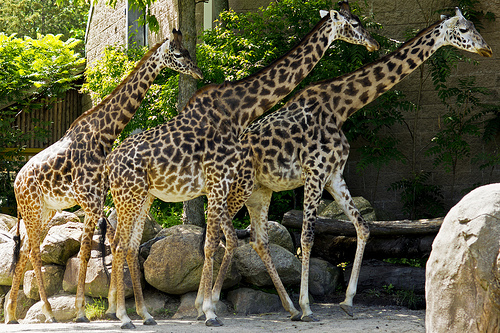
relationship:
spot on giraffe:
[404, 58, 419, 70] [194, 5, 494, 320]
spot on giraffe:
[223, 96, 240, 110] [98, 5, 382, 326]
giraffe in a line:
[221, 9, 481, 306] [7, 6, 491, 326]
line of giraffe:
[7, 6, 491, 326] [221, 9, 481, 306]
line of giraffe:
[7, 6, 491, 326] [98, 5, 382, 326]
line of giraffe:
[7, 6, 491, 326] [7, 27, 212, 319]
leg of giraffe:
[285, 184, 322, 323] [194, 5, 494, 320]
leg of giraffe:
[334, 193, 376, 311] [258, 23, 487, 314]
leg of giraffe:
[245, 185, 305, 321] [194, 5, 494, 320]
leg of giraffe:
[68, 215, 101, 324] [7, 27, 212, 319]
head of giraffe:
[163, 27, 205, 79] [7, 27, 212, 319]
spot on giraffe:
[303, 111, 315, 125] [163, 0, 435, 278]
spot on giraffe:
[270, 134, 286, 152] [163, 0, 435, 278]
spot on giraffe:
[329, 81, 343, 94] [163, 0, 435, 278]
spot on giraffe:
[334, 104, 347, 119] [163, 0, 435, 278]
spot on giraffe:
[318, 90, 332, 103] [163, 0, 435, 278]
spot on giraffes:
[273, 122, 290, 138] [13, 19, 477, 316]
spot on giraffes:
[332, 90, 342, 110] [13, 19, 477, 316]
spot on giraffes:
[325, 78, 344, 94] [13, 19, 477, 316]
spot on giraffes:
[357, 88, 372, 106] [13, 19, 477, 316]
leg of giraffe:
[327, 178, 374, 322] [191, 105, 468, 280]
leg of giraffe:
[290, 178, 330, 324] [191, 105, 468, 280]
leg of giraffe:
[248, 197, 301, 325] [191, 105, 468, 280]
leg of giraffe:
[109, 199, 139, 329] [98, 5, 382, 326]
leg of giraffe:
[216, 205, 237, 310] [98, 5, 382, 326]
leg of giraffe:
[327, 178, 374, 322] [221, 9, 481, 306]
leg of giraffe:
[294, 177, 325, 327] [221, 9, 481, 306]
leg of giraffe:
[244, 196, 300, 323] [221, 9, 481, 306]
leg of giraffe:
[203, 178, 222, 329] [221, 9, 481, 306]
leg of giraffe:
[111, 198, 134, 330] [98, 5, 382, 326]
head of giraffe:
[430, 6, 484, 61] [221, 9, 481, 306]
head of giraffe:
[307, 6, 382, 60] [98, 5, 382, 326]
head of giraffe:
[149, 25, 209, 82] [7, 27, 212, 319]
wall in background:
[362, 78, 499, 197] [7, 18, 481, 139]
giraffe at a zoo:
[221, 9, 481, 306] [5, 2, 484, 327]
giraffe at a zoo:
[98, 5, 382, 326] [5, 2, 484, 327]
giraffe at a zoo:
[7, 27, 212, 319] [5, 2, 484, 327]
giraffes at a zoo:
[13, 19, 477, 316] [5, 2, 484, 327]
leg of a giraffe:
[327, 180, 369, 317] [194, 5, 494, 320]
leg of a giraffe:
[298, 175, 318, 324] [194, 5, 494, 320]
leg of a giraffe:
[244, 196, 300, 323] [194, 5, 494, 320]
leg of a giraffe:
[107, 200, 137, 327] [98, 5, 382, 326]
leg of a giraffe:
[126, 210, 157, 329] [7, 27, 212, 319]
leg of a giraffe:
[16, 195, 59, 326] [7, 7, 197, 326]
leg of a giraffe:
[73, 196, 104, 321] [7, 7, 197, 326]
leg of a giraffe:
[106, 193, 136, 332] [7, 7, 197, 326]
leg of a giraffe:
[201, 192, 224, 331] [7, 7, 197, 326]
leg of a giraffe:
[327, 178, 374, 322] [239, 5, 483, 325]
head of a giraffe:
[429, 3, 480, 63] [221, 9, 481, 306]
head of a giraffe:
[310, 4, 384, 56] [98, 5, 382, 326]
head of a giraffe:
[145, 27, 207, 85] [7, 27, 212, 319]